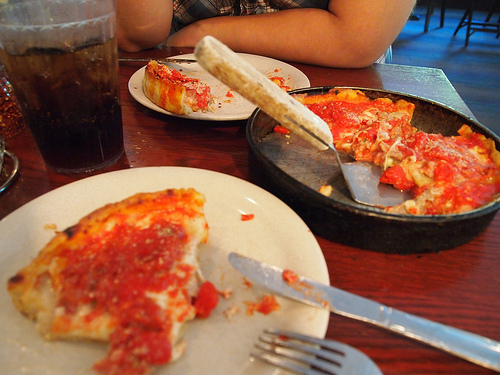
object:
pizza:
[291, 87, 500, 216]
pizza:
[142, 60, 210, 117]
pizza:
[7, 187, 216, 375]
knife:
[228, 252, 500, 371]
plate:
[128, 52, 311, 121]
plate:
[0, 165, 331, 374]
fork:
[249, 326, 384, 374]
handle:
[193, 35, 334, 152]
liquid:
[0, 33, 126, 174]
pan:
[244, 85, 499, 254]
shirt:
[170, 1, 331, 36]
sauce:
[58, 218, 190, 375]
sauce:
[306, 101, 499, 216]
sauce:
[153, 60, 213, 113]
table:
[0, 46, 499, 374]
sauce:
[282, 270, 333, 312]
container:
[0, 75, 23, 139]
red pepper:
[1, 89, 24, 141]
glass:
[0, 0, 127, 174]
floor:
[385, 1, 499, 138]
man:
[112, 1, 418, 70]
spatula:
[193, 35, 417, 208]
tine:
[263, 326, 346, 354]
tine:
[257, 336, 343, 363]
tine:
[252, 342, 341, 373]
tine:
[250, 352, 327, 375]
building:
[0, 3, 497, 63]